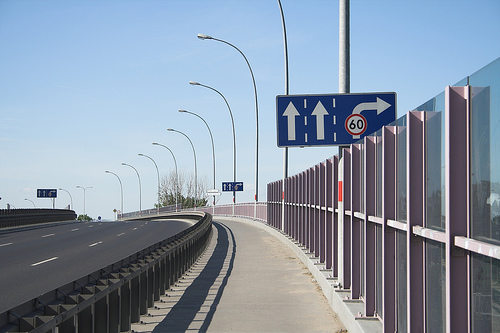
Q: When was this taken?
A: Daytime.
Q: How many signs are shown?
A: 3.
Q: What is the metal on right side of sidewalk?
A: Fence.